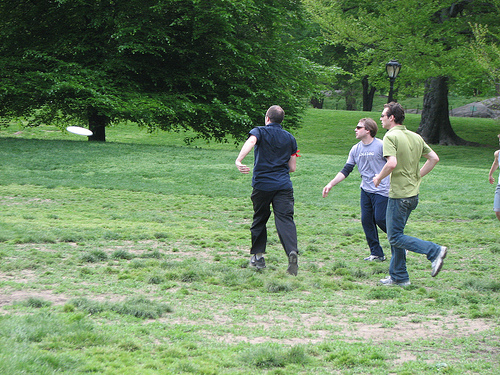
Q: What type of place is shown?
A: It is a field.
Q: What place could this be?
A: It is a field.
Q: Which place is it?
A: It is a field.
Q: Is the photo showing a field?
A: Yes, it is showing a field.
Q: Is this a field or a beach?
A: It is a field.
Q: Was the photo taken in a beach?
A: No, the picture was taken in a field.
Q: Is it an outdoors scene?
A: Yes, it is outdoors.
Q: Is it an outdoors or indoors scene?
A: It is outdoors.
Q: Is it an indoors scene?
A: No, it is outdoors.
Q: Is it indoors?
A: No, it is outdoors.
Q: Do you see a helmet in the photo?
A: No, there are no helmets.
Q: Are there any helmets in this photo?
A: No, there are no helmets.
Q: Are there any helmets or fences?
A: No, there are no helmets or fences.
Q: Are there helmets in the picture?
A: No, there are no helmets.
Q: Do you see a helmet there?
A: No, there are no helmets.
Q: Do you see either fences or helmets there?
A: No, there are no helmets or fences.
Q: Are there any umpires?
A: No, there are no umpires.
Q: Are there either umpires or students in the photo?
A: No, there are no umpires or students.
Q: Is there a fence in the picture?
A: No, there are no fences.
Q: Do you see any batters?
A: No, there are no batters.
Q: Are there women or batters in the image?
A: No, there are no batters or women.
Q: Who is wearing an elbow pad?
A: The man is wearing an elbow pad.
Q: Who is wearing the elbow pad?
A: The man is wearing an elbow pad.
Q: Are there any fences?
A: No, there are no fences.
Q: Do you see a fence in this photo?
A: No, there are no fences.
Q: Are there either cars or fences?
A: No, there are no fences or cars.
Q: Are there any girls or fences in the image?
A: No, there are no fences or girls.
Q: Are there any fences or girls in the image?
A: No, there are no fences or girls.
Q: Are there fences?
A: No, there are no fences.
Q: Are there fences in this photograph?
A: No, there are no fences.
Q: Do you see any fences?
A: No, there are no fences.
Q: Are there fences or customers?
A: No, there are no fences or customers.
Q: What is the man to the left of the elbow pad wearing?
A: The man is wearing a shirt.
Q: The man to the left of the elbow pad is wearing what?
A: The man is wearing a shirt.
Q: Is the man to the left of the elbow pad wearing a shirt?
A: Yes, the man is wearing a shirt.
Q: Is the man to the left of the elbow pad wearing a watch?
A: No, the man is wearing a shirt.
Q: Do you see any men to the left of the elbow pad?
A: Yes, there is a man to the left of the elbow pad.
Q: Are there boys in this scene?
A: No, there are no boys.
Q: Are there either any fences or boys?
A: No, there are no boys or fences.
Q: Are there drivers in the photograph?
A: No, there are no drivers.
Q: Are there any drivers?
A: No, there are no drivers.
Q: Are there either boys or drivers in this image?
A: No, there are no drivers or boys.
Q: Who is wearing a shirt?
A: The man is wearing a shirt.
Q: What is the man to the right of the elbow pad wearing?
A: The man is wearing a shirt.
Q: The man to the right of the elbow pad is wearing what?
A: The man is wearing a shirt.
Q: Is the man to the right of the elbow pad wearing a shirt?
A: Yes, the man is wearing a shirt.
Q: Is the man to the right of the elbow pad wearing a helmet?
A: No, the man is wearing a shirt.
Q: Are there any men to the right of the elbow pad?
A: Yes, there is a man to the right of the elbow pad.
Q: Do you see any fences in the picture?
A: No, there are no fences.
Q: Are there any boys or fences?
A: No, there are no fences or boys.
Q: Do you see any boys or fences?
A: No, there are no fences or boys.